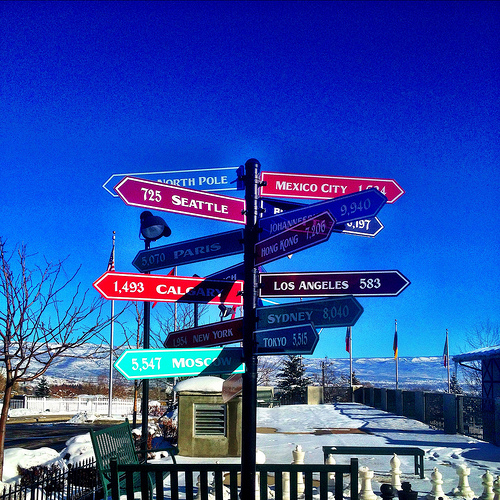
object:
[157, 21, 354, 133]
sky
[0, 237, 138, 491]
tree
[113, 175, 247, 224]
sign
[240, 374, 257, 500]
pole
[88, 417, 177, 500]
bench